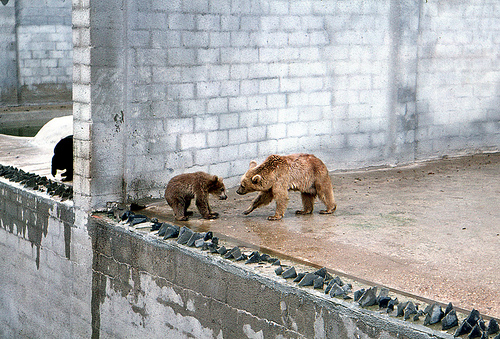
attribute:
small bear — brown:
[160, 168, 230, 223]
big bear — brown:
[231, 147, 341, 220]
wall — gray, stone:
[74, 0, 484, 209]